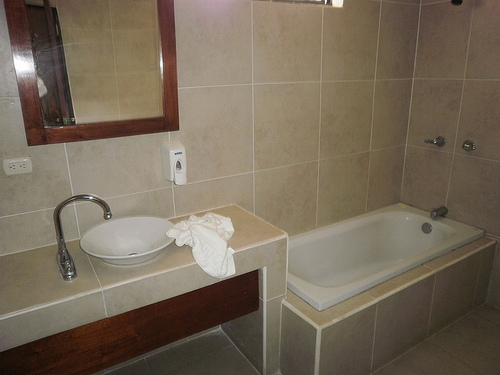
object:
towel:
[165, 211, 235, 279]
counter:
[0, 203, 289, 375]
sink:
[80, 216, 176, 265]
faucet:
[53, 193, 114, 280]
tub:
[287, 202, 486, 312]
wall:
[0, 0, 499, 261]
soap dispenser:
[161, 140, 187, 185]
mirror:
[5, 0, 164, 126]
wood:
[3, 0, 180, 147]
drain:
[126, 252, 139, 255]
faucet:
[430, 205, 448, 220]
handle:
[425, 136, 447, 147]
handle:
[462, 139, 476, 151]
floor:
[375, 303, 499, 374]